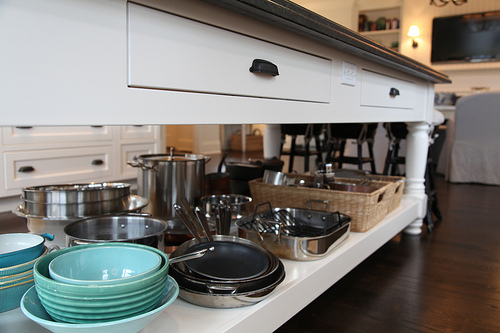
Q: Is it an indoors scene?
A: Yes, it is indoors.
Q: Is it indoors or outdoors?
A: It is indoors.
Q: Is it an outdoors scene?
A: No, it is indoors.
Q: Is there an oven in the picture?
A: No, there are no ovens.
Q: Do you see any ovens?
A: No, there are no ovens.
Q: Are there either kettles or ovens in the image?
A: No, there are no ovens or kettles.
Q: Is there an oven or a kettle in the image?
A: No, there are no ovens or kettles.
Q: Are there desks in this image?
A: No, there are no desks.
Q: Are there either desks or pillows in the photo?
A: No, there are no desks or pillows.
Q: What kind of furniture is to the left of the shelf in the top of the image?
A: The piece of furniture is a drawer.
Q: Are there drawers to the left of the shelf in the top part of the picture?
A: Yes, there is a drawer to the left of the shelf.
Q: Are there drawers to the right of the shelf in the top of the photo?
A: No, the drawer is to the left of the shelf.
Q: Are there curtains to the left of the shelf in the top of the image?
A: No, there is a drawer to the left of the shelf.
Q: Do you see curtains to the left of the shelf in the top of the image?
A: No, there is a drawer to the left of the shelf.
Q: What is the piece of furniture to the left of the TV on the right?
A: The piece of furniture is a drawer.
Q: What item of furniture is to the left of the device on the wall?
A: The piece of furniture is a drawer.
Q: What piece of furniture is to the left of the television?
A: The piece of furniture is a drawer.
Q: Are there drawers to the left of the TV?
A: Yes, there is a drawer to the left of the TV.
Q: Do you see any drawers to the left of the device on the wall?
A: Yes, there is a drawer to the left of the TV.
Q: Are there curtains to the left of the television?
A: No, there is a drawer to the left of the television.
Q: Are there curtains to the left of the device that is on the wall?
A: No, there is a drawer to the left of the television.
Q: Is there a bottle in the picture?
A: No, there are no bottles.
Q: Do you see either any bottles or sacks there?
A: No, there are no bottles or sacks.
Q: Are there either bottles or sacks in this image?
A: No, there are no bottles or sacks.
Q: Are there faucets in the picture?
A: No, there are no faucets.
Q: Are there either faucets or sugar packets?
A: No, there are no faucets or sugar packets.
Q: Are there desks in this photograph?
A: No, there are no desks.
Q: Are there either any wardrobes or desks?
A: No, there are no desks or wardrobes.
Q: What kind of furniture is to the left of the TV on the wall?
A: The piece of furniture is a shelf.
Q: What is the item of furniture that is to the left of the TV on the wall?
A: The piece of furniture is a shelf.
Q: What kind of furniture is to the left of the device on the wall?
A: The piece of furniture is a shelf.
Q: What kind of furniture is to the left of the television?
A: The piece of furniture is a shelf.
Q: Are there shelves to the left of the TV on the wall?
A: Yes, there is a shelf to the left of the television.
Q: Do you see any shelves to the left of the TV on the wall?
A: Yes, there is a shelf to the left of the television.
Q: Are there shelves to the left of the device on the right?
A: Yes, there is a shelf to the left of the television.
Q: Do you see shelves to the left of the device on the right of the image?
A: Yes, there is a shelf to the left of the television.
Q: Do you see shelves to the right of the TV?
A: No, the shelf is to the left of the TV.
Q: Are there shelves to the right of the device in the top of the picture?
A: No, the shelf is to the left of the TV.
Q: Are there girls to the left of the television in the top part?
A: No, there is a shelf to the left of the television.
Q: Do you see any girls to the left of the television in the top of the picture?
A: No, there is a shelf to the left of the television.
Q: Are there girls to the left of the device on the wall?
A: No, there is a shelf to the left of the television.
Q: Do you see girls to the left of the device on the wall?
A: No, there is a shelf to the left of the television.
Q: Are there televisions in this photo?
A: Yes, there is a television.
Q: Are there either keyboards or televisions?
A: Yes, there is a television.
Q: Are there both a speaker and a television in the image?
A: No, there is a television but no speakers.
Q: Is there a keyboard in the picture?
A: No, there are no keyboards.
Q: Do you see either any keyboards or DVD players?
A: No, there are no keyboards or DVD players.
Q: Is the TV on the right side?
A: Yes, the TV is on the right of the image.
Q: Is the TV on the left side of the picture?
A: No, the TV is on the right of the image.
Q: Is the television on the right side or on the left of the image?
A: The television is on the right of the image.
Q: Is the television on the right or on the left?
A: The television is on the right of the image.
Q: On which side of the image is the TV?
A: The TV is on the right of the image.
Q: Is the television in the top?
A: Yes, the television is in the top of the image.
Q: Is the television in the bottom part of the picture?
A: No, the television is in the top of the image.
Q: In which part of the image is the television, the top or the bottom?
A: The television is in the top of the image.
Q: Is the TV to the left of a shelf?
A: No, the TV is to the right of a shelf.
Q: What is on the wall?
A: The television is on the wall.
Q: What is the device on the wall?
A: The device is a television.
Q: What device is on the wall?
A: The device is a television.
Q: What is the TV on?
A: The TV is on the wall.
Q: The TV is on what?
A: The TV is on the wall.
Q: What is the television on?
A: The TV is on the wall.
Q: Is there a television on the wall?
A: Yes, there is a television on the wall.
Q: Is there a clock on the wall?
A: No, there is a television on the wall.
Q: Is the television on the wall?
A: Yes, the television is on the wall.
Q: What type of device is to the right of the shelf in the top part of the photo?
A: The device is a television.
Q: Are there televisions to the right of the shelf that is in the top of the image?
A: Yes, there is a television to the right of the shelf.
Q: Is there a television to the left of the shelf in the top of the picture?
A: No, the television is to the right of the shelf.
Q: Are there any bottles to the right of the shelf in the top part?
A: No, there is a television to the right of the shelf.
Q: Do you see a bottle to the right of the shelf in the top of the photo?
A: No, there is a television to the right of the shelf.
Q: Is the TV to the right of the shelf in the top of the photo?
A: Yes, the TV is to the right of the shelf.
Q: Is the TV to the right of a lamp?
A: No, the TV is to the right of the shelf.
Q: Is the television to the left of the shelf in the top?
A: No, the television is to the right of the shelf.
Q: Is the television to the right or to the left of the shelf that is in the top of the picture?
A: The television is to the right of the shelf.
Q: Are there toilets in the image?
A: No, there are no toilets.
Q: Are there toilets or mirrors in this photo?
A: No, there are no toilets or mirrors.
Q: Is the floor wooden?
A: Yes, the floor is wooden.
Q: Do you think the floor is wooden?
A: Yes, the floor is wooden.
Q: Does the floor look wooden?
A: Yes, the floor is wooden.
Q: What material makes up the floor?
A: The floor is made of wood.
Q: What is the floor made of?
A: The floor is made of wood.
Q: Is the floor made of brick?
A: No, the floor is made of wood.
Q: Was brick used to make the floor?
A: No, the floor is made of wood.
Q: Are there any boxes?
A: No, there are no boxes.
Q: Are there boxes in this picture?
A: No, there are no boxes.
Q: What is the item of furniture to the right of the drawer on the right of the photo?
A: The piece of furniture is a shelf.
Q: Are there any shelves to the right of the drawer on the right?
A: Yes, there is a shelf to the right of the drawer.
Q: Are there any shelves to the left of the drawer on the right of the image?
A: No, the shelf is to the right of the drawer.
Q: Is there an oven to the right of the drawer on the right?
A: No, there is a shelf to the right of the drawer.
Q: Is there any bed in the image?
A: No, there are no beds.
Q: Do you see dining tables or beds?
A: No, there are no beds or dining tables.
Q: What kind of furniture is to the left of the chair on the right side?
A: The piece of furniture is a shelf.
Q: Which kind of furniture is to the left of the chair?
A: The piece of furniture is a shelf.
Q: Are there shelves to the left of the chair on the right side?
A: Yes, there is a shelf to the left of the chair.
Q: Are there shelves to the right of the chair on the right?
A: No, the shelf is to the left of the chair.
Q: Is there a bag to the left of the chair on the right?
A: No, there is a shelf to the left of the chair.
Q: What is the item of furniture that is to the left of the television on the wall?
A: The piece of furniture is a shelf.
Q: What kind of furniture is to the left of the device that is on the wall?
A: The piece of furniture is a shelf.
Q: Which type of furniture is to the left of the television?
A: The piece of furniture is a shelf.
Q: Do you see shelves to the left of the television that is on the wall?
A: Yes, there is a shelf to the left of the television.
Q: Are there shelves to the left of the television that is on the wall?
A: Yes, there is a shelf to the left of the television.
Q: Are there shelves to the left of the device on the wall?
A: Yes, there is a shelf to the left of the television.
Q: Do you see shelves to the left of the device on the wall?
A: Yes, there is a shelf to the left of the television.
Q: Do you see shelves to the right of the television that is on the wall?
A: No, the shelf is to the left of the television.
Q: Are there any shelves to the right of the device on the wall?
A: No, the shelf is to the left of the television.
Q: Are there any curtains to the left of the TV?
A: No, there is a shelf to the left of the TV.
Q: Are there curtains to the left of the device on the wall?
A: No, there is a shelf to the left of the TV.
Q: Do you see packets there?
A: No, there are no packets.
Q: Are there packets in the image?
A: No, there are no packets.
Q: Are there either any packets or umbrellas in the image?
A: No, there are no packets or umbrellas.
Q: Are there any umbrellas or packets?
A: No, there are no packets or umbrellas.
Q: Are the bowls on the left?
A: Yes, the bowls are on the left of the image.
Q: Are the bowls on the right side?
A: No, the bowls are on the left of the image.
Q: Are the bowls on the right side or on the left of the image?
A: The bowls are on the left of the image.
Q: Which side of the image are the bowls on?
A: The bowls are on the left of the image.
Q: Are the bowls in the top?
A: No, the bowls are in the bottom of the image.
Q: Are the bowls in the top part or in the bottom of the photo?
A: The bowls are in the bottom of the image.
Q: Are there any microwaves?
A: No, there are no microwaves.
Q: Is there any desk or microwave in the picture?
A: No, there are no microwaves or desks.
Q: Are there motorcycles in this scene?
A: No, there are no motorcycles.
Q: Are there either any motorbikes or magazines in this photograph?
A: No, there are no motorbikes or magazines.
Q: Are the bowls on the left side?
A: Yes, the bowls are on the left of the image.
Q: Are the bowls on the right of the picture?
A: No, the bowls are on the left of the image.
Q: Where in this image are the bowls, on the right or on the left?
A: The bowls are on the left of the image.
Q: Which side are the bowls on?
A: The bowls are on the left of the image.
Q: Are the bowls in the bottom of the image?
A: Yes, the bowls are in the bottom of the image.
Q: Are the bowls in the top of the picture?
A: No, the bowls are in the bottom of the image.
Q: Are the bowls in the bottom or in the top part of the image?
A: The bowls are in the bottom of the image.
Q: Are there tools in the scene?
A: No, there are no tools.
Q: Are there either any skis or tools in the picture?
A: No, there are no tools or skis.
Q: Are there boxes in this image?
A: No, there are no boxes.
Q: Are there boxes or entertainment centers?
A: No, there are no boxes or entertainment centers.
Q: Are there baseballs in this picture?
A: No, there are no baseballs.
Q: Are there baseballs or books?
A: No, there are no baseballs or books.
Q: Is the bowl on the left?
A: Yes, the bowl is on the left of the image.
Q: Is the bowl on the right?
A: No, the bowl is on the left of the image.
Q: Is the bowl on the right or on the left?
A: The bowl is on the left of the image.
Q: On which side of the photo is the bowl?
A: The bowl is on the left of the image.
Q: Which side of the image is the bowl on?
A: The bowl is on the left of the image.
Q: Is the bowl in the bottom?
A: Yes, the bowl is in the bottom of the image.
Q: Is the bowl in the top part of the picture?
A: No, the bowl is in the bottom of the image.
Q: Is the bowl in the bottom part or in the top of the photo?
A: The bowl is in the bottom of the image.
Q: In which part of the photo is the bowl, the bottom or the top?
A: The bowl is in the bottom of the image.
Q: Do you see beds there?
A: No, there are no beds.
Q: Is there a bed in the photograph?
A: No, there are no beds.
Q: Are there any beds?
A: No, there are no beds.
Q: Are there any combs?
A: No, there are no combs.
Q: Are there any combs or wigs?
A: No, there are no combs or wigs.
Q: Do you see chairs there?
A: Yes, there is a chair.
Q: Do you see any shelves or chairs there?
A: Yes, there is a chair.